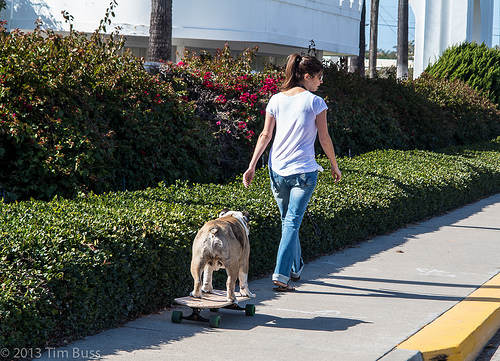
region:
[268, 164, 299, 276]
The woman is wearing blue jeans.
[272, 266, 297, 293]
The woman is wearing sandals.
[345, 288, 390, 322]
The pavement is gray.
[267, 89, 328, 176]
The woman is wearing a white shirt.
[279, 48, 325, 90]
The woman has brown hair.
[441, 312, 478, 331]
The curb is yellow in color.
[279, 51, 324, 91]
The woman is wearing glasses.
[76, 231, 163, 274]
The bushes in the forefront are green.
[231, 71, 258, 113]
The flowers are red in color.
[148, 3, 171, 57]
The tree trunk is brown in color.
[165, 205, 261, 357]
Dog riding a skateboard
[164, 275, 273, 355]
Brown wooden skate board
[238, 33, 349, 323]
Woman walking on pavement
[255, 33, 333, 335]
Woman wearing white shirt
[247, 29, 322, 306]
Woman wearing jean pants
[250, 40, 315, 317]
Woman wearing flip flpos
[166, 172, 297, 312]
Green shrubs beside sidewalk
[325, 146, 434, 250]
Green shrubs beside sidewalk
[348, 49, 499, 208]
Green shrubs beside sidewalk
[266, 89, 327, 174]
the girl is wearing a short sleeve shirt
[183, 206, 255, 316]
the dog is on a skateboard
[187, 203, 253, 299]
the dog is a bull dog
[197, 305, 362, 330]
a shadow is on the pavement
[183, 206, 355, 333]
the dog is casting a shadow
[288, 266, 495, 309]
teh girl is casting a shadow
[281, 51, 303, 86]
the girl has a pony tail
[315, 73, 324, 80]
the girl is wearing glasses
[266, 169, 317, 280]
the girl is wearing jeans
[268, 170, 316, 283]
the jeans are blue in color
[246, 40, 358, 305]
A woman walking down the sidewalk.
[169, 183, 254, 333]
A dog on a skateboard.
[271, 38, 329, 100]
A woman with dark hair.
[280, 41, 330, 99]
A woman's hair pulled back into a ponytail.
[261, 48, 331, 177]
Woman wearing a white tee shirt.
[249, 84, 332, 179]
A short sleeve shirt.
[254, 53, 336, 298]
A woman wearing a pair of jeans.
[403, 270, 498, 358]
Yellow curbing on the edge of sidewalk.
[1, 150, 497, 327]
A row of green shrubbery.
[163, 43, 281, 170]
A plant with red flowers.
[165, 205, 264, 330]
Dog standing on skateboard.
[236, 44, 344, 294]
Woman walking down sidewalk.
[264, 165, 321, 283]
Woman dressed in blue jeans.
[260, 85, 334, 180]
Woman dressed in white t-shirt.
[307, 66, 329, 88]
Woman wearing sunglasses over eyes.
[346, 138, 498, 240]
Shrubbery next to sidewalk.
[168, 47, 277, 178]
Pink flowers growing on bush.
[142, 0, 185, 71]
Trunk of tree growing next to shrubbery.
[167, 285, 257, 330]
Skateboard under dog's feet.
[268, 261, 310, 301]
Woman wearing sandals on feet.